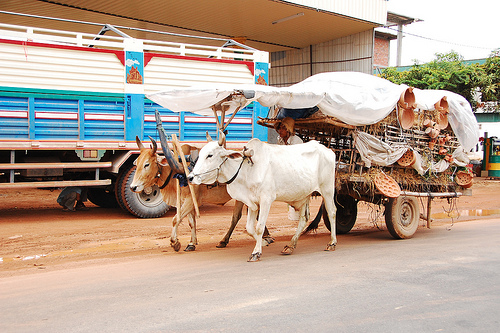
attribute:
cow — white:
[193, 139, 342, 248]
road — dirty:
[218, 270, 498, 332]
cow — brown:
[121, 141, 206, 252]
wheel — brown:
[386, 191, 424, 239]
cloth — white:
[236, 66, 487, 141]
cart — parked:
[2, 14, 252, 225]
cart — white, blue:
[1, 9, 279, 221]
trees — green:
[398, 49, 496, 96]